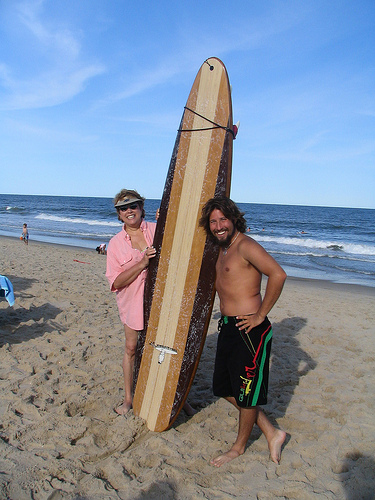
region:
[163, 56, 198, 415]
brown surf board held by men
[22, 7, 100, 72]
white clouds in blue sky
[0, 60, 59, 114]
white clouds in blue sky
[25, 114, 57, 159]
white clouds in blue sky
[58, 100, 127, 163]
white clouds in blue sky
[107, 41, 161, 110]
white clouds in blue sky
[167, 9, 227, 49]
white clouds in blue sky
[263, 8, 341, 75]
white clouds in blue sky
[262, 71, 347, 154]
white clouds in blue sky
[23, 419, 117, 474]
tan sand on beach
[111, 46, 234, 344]
These people are standing with a surfboard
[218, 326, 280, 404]
The man has green, black, and red trunks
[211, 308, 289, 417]
The man is wearing swim trunks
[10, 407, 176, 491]
The ground here is made of sand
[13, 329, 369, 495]
This is on a beach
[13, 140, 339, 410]
This setting is along a coast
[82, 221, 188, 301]
The woman is wearing pink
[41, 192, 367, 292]
The ocean is very blue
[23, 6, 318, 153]
The weather is mostly clear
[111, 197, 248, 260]
Both people are smiling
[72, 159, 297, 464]
two people posing for a picture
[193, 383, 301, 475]
the man is bare foot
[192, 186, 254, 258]
the man is smiling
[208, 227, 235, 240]
the teeth are white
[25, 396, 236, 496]
foot prints in the sand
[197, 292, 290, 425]
the man is wearing shorts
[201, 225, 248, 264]
the man is wearing a chain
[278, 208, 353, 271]
the water is in motion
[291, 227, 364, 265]
the waves are white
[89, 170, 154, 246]
woman is wearing a visor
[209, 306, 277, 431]
Man wearing black shorts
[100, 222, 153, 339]
Man wearing pink shirt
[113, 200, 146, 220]
woman in sunglasses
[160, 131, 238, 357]
two people holding a surf board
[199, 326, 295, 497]
Man standing in the sand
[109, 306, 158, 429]
woman standing in the sand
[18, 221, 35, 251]
child playing in the sand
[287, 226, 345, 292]
waves crashing on the beach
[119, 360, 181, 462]
surf board in the sand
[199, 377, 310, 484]
man barefoot in the sand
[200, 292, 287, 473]
man wearing a short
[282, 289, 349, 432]
shadows on the ground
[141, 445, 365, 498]
shadows on the ground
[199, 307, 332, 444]
shadows on the ground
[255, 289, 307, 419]
shadows on the ground